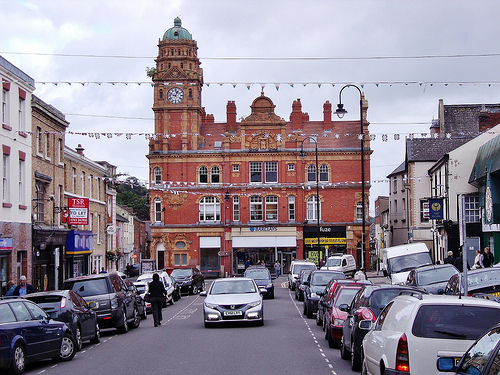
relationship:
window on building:
[194, 162, 209, 183] [142, 12, 377, 283]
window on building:
[207, 162, 221, 184] [142, 12, 377, 283]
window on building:
[193, 187, 222, 226] [142, 12, 377, 283]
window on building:
[247, 156, 264, 183] [142, 12, 377, 283]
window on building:
[302, 157, 317, 184] [142, 12, 377, 283]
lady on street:
[144, 273, 168, 327] [0, 261, 498, 373]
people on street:
[12, 275, 39, 299] [0, 261, 498, 373]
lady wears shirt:
[144, 273, 168, 327] [146, 280, 165, 299]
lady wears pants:
[144, 273, 168, 327] [152, 296, 164, 322]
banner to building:
[67, 197, 88, 225] [31, 93, 70, 293]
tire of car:
[52, 328, 79, 363] [1, 294, 82, 374]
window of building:
[264, 160, 279, 185] [136, 6, 384, 250]